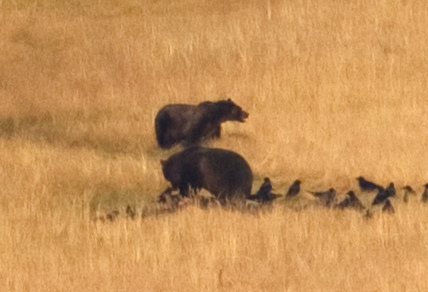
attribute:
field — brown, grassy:
[3, 0, 423, 288]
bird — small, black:
[284, 174, 303, 202]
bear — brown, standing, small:
[156, 97, 252, 148]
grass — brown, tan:
[1, 1, 428, 291]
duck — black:
[257, 174, 275, 200]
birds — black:
[250, 177, 427, 221]